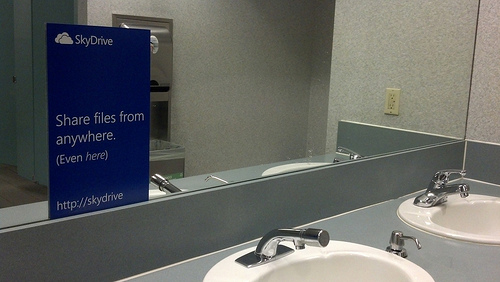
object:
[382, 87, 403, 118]
socket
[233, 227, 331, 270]
faucet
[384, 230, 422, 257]
soap dispenser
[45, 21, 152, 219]
sign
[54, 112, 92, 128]
word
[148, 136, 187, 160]
bag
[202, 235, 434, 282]
sink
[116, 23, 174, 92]
towel dispenser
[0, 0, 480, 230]
mirror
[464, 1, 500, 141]
wall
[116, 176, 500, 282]
counter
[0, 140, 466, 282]
backsplash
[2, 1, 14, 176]
doorway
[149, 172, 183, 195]
faucet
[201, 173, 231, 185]
soap dispenser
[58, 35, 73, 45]
cloud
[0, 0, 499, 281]
photo